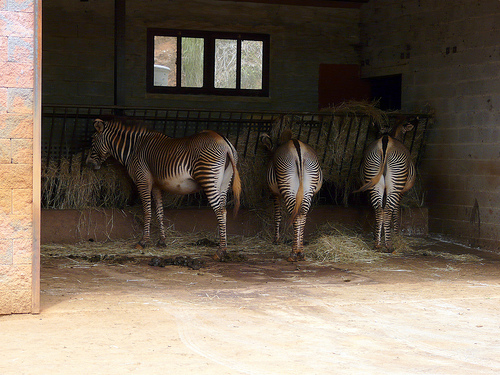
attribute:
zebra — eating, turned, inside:
[86, 113, 244, 255]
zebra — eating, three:
[260, 126, 324, 265]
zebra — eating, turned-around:
[356, 123, 419, 257]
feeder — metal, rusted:
[45, 113, 435, 188]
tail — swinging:
[353, 138, 388, 197]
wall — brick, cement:
[0, 0, 499, 314]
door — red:
[318, 64, 362, 115]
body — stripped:
[150, 136, 201, 194]